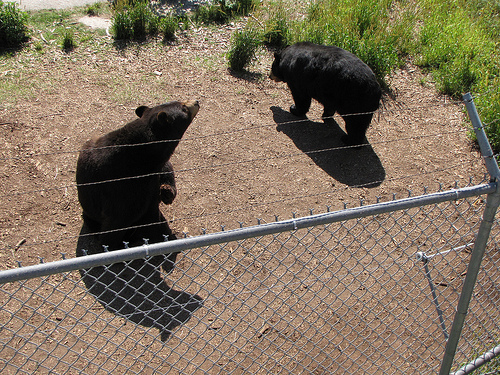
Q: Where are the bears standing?
A: Behind the fence.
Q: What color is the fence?
A: Silver.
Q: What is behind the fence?
A: 2 bears.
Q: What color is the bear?
A: Brown.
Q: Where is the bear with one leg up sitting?
A: On the ground.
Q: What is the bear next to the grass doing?
A: Walking.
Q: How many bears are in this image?
A: 2.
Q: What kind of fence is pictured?
A: Chain link fence.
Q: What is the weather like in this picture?
A: Sunny.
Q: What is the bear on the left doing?
A: Scratching itself.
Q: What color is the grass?
A: Green.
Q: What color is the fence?
A: Gray.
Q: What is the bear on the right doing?
A: Standing.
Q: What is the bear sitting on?
A: Dirt.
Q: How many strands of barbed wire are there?
A: 3.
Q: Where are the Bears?
A: Fenced in.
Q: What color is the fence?
A: Silver.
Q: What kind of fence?
A: Chain link.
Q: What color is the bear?
A: Black.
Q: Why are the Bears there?
A: It's a zoo.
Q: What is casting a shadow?
A: Both bears.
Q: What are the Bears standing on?
A: Dirt.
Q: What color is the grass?
A: Green.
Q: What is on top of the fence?
A: Barbed wire.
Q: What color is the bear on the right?
A: Black.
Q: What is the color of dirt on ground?
A: Brown.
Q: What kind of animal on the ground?
A: Bear.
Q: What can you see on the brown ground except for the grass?
A: Bear's shadow.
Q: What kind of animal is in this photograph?
A: Bears.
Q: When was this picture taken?
A: Day time.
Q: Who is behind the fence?
A: The bears.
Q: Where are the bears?
A: Behind the fence.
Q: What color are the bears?
A: Black.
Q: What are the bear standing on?
A: Tan Bark.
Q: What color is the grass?
A: Green.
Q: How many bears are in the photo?
A: Two.